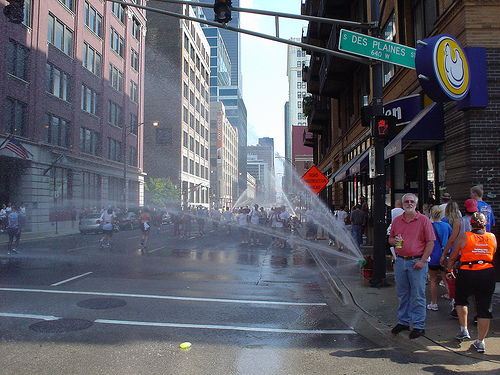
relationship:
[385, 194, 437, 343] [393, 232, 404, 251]
man holding bottle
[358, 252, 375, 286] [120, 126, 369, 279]
hydrant spraying water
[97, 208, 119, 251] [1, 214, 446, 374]
people on street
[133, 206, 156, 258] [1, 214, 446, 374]
people on street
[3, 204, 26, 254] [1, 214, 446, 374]
people on street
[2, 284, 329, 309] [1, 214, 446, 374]
lines on street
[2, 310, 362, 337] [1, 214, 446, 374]
lines on street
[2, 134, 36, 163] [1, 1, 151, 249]
flag on building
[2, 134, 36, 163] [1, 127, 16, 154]
flag on pole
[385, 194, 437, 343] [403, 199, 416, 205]
man wearing glasses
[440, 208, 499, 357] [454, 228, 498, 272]
woman in shirt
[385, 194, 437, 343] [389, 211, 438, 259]
man in shirt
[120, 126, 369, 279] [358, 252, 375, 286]
water out of hydrant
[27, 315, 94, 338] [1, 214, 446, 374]
covers in street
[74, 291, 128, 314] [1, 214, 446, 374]
covers in street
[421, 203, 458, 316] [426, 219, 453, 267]
woman in shirt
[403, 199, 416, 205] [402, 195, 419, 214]
glasses on face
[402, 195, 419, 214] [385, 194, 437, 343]
face of man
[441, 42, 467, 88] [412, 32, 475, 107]
logo on sign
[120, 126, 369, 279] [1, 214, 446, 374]
water on street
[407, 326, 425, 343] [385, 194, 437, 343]
shoe on man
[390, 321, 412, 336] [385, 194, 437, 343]
shoe on man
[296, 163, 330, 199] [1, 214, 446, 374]
sign above street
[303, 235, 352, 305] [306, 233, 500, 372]
curb of sidewalk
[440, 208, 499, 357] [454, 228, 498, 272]
woman wearing shirt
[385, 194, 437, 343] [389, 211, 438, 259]
man wearing shirt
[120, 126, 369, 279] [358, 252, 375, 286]
water from hydrant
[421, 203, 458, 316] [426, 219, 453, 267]
woman with shirt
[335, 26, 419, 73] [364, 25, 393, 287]
sign over pole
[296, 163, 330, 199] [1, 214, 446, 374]
sign on side of street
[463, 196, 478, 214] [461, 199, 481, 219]
cap on head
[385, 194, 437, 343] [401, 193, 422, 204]
man has hair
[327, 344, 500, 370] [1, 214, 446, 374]
shadow on street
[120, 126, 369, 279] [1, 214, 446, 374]
water in street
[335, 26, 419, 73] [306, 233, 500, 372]
sign above sidewalk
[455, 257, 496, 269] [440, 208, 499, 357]
band on woman